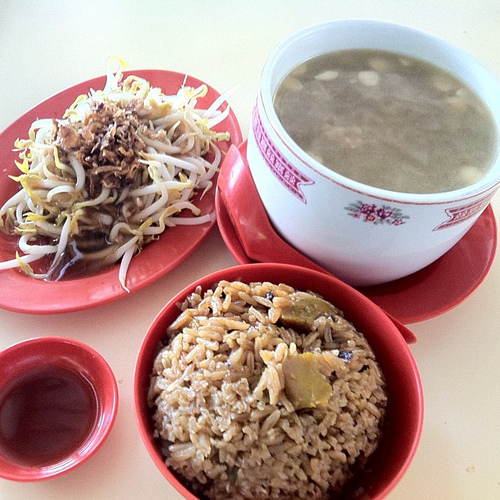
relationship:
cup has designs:
[244, 19, 496, 290] [251, 117, 485, 271]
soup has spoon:
[279, 34, 499, 237] [218, 138, 430, 349]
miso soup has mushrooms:
[279, 34, 499, 237] [312, 89, 475, 168]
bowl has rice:
[113, 248, 436, 497] [182, 295, 361, 472]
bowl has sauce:
[1, 323, 132, 473] [15, 370, 75, 408]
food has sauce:
[29, 3, 497, 491] [15, 370, 75, 408]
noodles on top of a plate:
[11, 136, 71, 266] [1, 48, 254, 302]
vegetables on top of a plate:
[52, 121, 155, 225] [1, 48, 254, 302]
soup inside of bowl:
[279, 34, 499, 237] [234, 10, 500, 291]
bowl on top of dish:
[234, 10, 500, 291] [210, 125, 494, 323]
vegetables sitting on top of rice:
[263, 288, 349, 419] [182, 295, 361, 472]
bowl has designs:
[234, 10, 500, 291] [251, 117, 485, 271]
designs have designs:
[251, 117, 485, 271] [343, 195, 410, 231]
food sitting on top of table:
[0, 3, 498, 490] [1, 10, 497, 497]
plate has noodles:
[1, 48, 254, 302] [11, 136, 71, 266]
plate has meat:
[1, 48, 254, 302] [68, 95, 154, 175]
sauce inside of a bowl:
[15, 370, 75, 408] [1, 323, 132, 473]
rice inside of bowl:
[182, 295, 361, 472] [113, 248, 436, 497]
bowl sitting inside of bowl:
[234, 10, 500, 291] [216, 87, 499, 343]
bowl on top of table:
[1, 323, 132, 473] [1, 10, 497, 497]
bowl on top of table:
[113, 248, 436, 497] [1, 10, 497, 497]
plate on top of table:
[1, 48, 254, 302] [1, 10, 497, 497]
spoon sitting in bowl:
[218, 138, 430, 349] [216, 87, 499, 343]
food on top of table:
[29, 3, 497, 491] [1, 10, 497, 497]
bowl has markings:
[234, 10, 500, 291] [249, 98, 499, 231]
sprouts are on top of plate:
[9, 69, 241, 279] [1, 48, 254, 302]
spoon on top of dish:
[218, 138, 430, 349] [210, 125, 499, 305]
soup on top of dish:
[279, 34, 499, 237] [210, 125, 499, 305]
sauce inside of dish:
[15, 370, 75, 408] [5, 320, 132, 484]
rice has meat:
[182, 295, 361, 472] [258, 288, 354, 437]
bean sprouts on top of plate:
[12, 87, 239, 269] [1, 48, 254, 302]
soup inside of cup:
[279, 34, 499, 237] [244, 19, 496, 290]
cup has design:
[244, 19, 496, 290] [251, 117, 485, 271]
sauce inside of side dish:
[15, 370, 75, 408] [1, 323, 132, 473]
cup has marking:
[244, 19, 496, 290] [251, 117, 485, 271]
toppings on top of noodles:
[70, 97, 153, 200] [11, 136, 71, 266]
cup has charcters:
[244, 19, 496, 290] [251, 97, 317, 206]